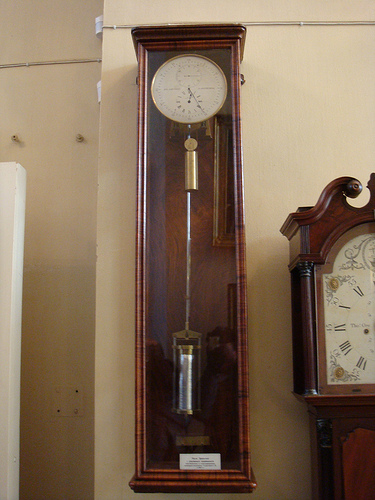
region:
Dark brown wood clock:
[278, 169, 372, 498]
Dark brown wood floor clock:
[278, 167, 374, 498]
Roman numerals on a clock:
[333, 276, 373, 377]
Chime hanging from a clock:
[168, 121, 210, 416]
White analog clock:
[148, 51, 228, 123]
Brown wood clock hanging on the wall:
[123, 22, 256, 496]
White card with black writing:
[176, 449, 222, 473]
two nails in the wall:
[8, 129, 84, 148]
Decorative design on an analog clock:
[325, 347, 360, 385]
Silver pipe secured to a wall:
[0, 13, 373, 76]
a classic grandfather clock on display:
[270, 165, 370, 498]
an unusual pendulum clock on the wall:
[123, 16, 255, 496]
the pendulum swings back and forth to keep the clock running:
[161, 317, 201, 422]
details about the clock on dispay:
[173, 450, 223, 470]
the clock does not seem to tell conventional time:
[148, 50, 228, 127]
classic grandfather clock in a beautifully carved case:
[276, 164, 374, 499]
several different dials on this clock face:
[150, 50, 232, 129]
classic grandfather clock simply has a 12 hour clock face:
[320, 262, 373, 386]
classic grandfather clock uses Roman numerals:
[322, 265, 374, 385]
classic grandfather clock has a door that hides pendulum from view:
[313, 401, 374, 496]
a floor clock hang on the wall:
[122, 12, 262, 498]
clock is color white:
[146, 47, 232, 128]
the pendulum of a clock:
[170, 126, 210, 454]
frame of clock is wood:
[122, 16, 262, 497]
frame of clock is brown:
[126, 16, 263, 498]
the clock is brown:
[275, 151, 373, 498]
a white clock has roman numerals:
[316, 216, 370, 391]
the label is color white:
[167, 442, 230, 478]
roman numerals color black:
[326, 274, 371, 383]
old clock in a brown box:
[273, 165, 373, 497]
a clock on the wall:
[125, 23, 256, 492]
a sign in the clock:
[176, 450, 222, 474]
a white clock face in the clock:
[151, 51, 226, 130]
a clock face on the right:
[275, 161, 374, 410]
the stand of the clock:
[300, 403, 373, 496]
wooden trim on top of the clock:
[275, 165, 369, 244]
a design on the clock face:
[334, 232, 371, 273]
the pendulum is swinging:
[165, 323, 211, 419]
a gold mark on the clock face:
[328, 352, 358, 381]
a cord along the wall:
[0, 17, 373, 74]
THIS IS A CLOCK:
[300, 228, 373, 391]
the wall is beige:
[34, 287, 68, 336]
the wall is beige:
[255, 355, 286, 436]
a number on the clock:
[338, 278, 371, 303]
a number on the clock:
[325, 312, 351, 342]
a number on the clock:
[331, 332, 357, 363]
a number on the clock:
[347, 349, 371, 371]